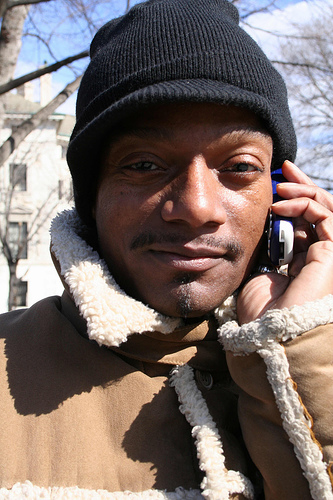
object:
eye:
[122, 156, 171, 178]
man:
[3, 1, 330, 498]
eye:
[220, 154, 265, 178]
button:
[193, 365, 219, 392]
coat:
[4, 260, 329, 496]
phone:
[267, 165, 294, 265]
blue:
[269, 219, 279, 258]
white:
[279, 223, 292, 263]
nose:
[165, 152, 223, 231]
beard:
[145, 267, 235, 318]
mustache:
[127, 228, 249, 258]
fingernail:
[282, 155, 299, 175]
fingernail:
[272, 181, 296, 191]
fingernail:
[271, 196, 291, 214]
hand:
[256, 158, 332, 320]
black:
[141, 20, 188, 42]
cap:
[73, 0, 300, 154]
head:
[67, 0, 287, 310]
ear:
[269, 158, 285, 225]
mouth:
[148, 243, 238, 279]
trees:
[297, 2, 333, 160]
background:
[5, 2, 332, 137]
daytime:
[285, 2, 331, 166]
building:
[2, 64, 66, 289]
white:
[86, 287, 126, 332]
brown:
[61, 408, 114, 445]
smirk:
[122, 223, 248, 293]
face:
[95, 104, 273, 305]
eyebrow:
[217, 126, 269, 154]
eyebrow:
[112, 120, 172, 149]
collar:
[49, 285, 135, 341]